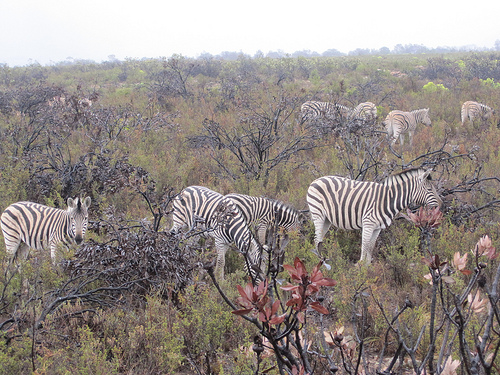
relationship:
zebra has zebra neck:
[305, 166, 443, 270] [382, 170, 417, 224]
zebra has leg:
[300, 154, 455, 274] [354, 228, 381, 265]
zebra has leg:
[305, 166, 443, 270] [311, 215, 345, 260]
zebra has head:
[105, 174, 325, 261] [228, 210, 319, 292]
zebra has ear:
[0, 186, 109, 272] [80, 187, 88, 212]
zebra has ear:
[305, 166, 443, 270] [417, 165, 433, 181]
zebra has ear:
[0, 195, 92, 266] [82, 195, 92, 207]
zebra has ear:
[383, 106, 431, 146] [65, 196, 75, 208]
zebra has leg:
[210, 187, 305, 289] [210, 239, 226, 286]